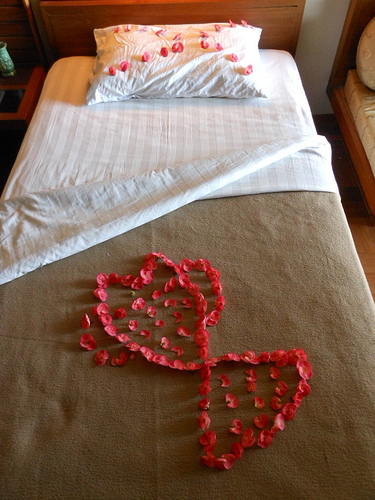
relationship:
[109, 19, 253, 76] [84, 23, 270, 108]
flowers on pillow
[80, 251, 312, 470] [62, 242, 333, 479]
flowers making sign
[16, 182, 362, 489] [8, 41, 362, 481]
bedspread on bed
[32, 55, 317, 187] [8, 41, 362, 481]
sheets on bed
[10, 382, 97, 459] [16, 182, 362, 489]
indention on bedspread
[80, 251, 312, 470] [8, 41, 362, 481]
flowers on bed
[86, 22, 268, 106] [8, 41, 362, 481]
pillow on bed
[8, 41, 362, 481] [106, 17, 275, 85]
bed with petals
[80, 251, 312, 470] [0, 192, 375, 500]
flowers over bedspread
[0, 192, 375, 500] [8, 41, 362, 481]
bedspread on bed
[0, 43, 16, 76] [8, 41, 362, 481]
vase to left bed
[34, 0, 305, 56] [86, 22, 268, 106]
headboard behind pillow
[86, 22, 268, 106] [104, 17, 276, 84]
pillow with flowers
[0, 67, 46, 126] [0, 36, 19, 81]
nightstand with vase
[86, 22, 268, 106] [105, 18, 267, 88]
pillow with flowers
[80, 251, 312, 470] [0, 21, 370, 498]
flowers on bed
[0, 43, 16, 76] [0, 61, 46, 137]
vase on nightstand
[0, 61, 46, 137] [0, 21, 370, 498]
nightstand beside bed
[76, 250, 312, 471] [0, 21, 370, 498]
flowers on bed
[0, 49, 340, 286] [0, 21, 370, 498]
sheets on bed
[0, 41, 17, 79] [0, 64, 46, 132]
vase on table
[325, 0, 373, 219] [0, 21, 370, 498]
bed next to bed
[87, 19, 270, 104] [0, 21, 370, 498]
pillow on bed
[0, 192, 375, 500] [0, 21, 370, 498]
bedspread on bed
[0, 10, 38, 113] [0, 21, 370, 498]
stand by bed